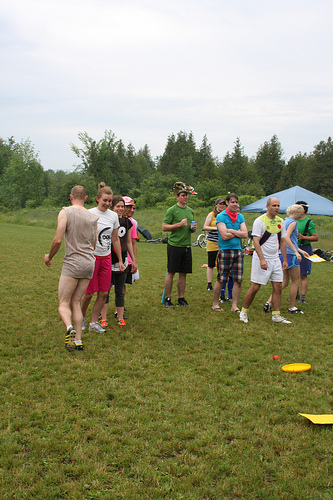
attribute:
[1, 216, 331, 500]
grass — green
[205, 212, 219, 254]
top — yellow, orange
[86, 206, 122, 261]
top — white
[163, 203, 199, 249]
top — green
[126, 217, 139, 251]
top — pink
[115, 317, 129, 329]
shoe — orange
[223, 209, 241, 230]
scarf — red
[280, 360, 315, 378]
frisbee — yellow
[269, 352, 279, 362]
ball — red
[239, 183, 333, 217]
tent — blue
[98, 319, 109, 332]
sneaker — orange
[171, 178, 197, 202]
hat — silly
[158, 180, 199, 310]
person — man, light-skinned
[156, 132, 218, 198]
tree — green, tall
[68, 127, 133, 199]
tree — green, tall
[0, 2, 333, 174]
sky — cloudy, blue, white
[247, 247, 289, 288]
shorts — white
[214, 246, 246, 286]
shorts — checkered, plaid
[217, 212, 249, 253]
shirt — blue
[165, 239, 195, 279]
shorts — black